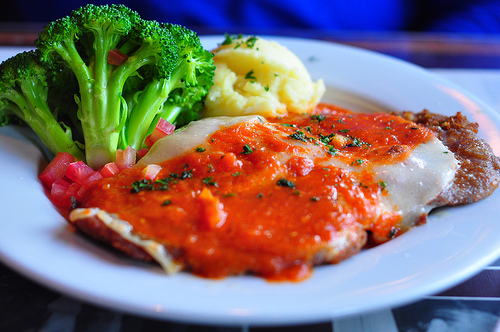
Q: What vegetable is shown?
A: Broccoli.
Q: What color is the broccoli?
A: Green.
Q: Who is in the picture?
A: No one.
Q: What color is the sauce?
A: Red.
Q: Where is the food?
A: On the plate.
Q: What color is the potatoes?
A: White.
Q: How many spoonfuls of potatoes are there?
A: 1.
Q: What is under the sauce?
A: Cheese.